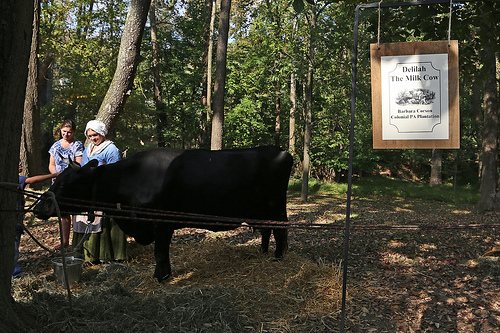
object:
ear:
[77, 159, 99, 177]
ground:
[291, 194, 497, 222]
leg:
[151, 225, 175, 284]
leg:
[248, 210, 274, 253]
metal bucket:
[52, 255, 84, 287]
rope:
[16, 217, 96, 259]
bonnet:
[84, 119, 109, 137]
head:
[59, 119, 76, 139]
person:
[48, 120, 82, 175]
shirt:
[48, 139, 84, 174]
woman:
[73, 116, 126, 263]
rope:
[0, 185, 500, 231]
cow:
[31, 144, 293, 281]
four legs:
[131, 209, 289, 284]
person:
[81, 121, 120, 206]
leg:
[267, 207, 288, 262]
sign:
[370, 40, 460, 149]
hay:
[126, 240, 350, 325]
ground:
[18, 220, 498, 332]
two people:
[46, 115, 128, 264]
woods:
[0, 0, 500, 189]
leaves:
[227, 42, 276, 144]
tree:
[275, 82, 281, 144]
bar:
[338, 0, 500, 331]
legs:
[51, 215, 71, 250]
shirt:
[81, 139, 121, 167]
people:
[13, 157, 64, 279]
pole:
[338, 2, 361, 332]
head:
[83, 120, 109, 146]